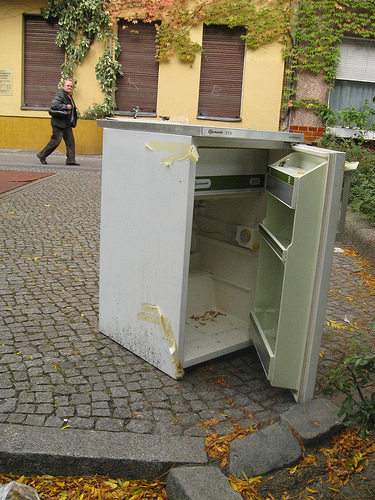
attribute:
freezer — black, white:
[85, 108, 348, 404]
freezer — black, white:
[189, 142, 270, 196]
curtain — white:
[324, 79, 373, 136]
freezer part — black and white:
[192, 168, 265, 192]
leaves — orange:
[31, 477, 166, 497]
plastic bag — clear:
[4, 481, 40, 498]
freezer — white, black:
[189, 140, 308, 214]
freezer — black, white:
[98, 114, 359, 404]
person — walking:
[36, 78, 78, 166]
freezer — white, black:
[191, 158, 267, 196]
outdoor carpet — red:
[0, 167, 54, 200]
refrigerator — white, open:
[103, 120, 341, 398]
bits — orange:
[191, 309, 221, 326]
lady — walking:
[46, 77, 84, 157]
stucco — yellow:
[2, 5, 291, 129]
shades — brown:
[198, 22, 240, 115]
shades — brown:
[114, 18, 156, 113]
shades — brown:
[24, 14, 64, 108]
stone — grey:
[45, 355, 173, 430]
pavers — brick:
[12, 289, 104, 382]